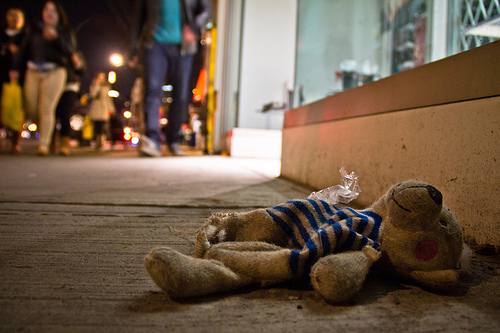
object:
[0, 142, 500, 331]
sidewalk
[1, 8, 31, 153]
person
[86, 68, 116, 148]
person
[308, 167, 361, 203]
stuffing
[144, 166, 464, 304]
teddy bear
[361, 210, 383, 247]
stripes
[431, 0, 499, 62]
door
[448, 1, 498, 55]
gate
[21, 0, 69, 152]
woman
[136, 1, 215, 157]
man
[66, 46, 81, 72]
bag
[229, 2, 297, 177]
entrance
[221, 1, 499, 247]
store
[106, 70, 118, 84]
light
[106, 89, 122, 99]
light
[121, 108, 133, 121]
light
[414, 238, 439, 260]
cheek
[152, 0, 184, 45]
shirt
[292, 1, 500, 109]
window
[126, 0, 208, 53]
jacket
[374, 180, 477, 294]
head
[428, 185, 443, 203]
nose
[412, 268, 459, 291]
ear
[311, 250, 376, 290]
arm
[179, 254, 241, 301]
leg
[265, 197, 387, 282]
shirt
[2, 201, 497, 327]
slab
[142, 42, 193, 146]
jeans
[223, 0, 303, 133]
side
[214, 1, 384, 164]
building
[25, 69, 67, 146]
pants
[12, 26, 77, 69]
sweater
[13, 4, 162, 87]
sky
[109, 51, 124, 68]
street lights